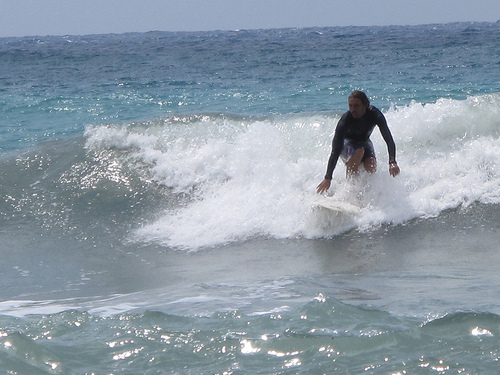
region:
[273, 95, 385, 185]
Person in water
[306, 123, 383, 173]
Person wearing black long sleeve shirt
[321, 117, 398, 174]
Person wearing dark bottoms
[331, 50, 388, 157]
Person has dark hair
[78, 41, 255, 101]
Water is blue and clear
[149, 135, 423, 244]
Waves rolling in by person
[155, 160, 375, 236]
Wave has white cap on it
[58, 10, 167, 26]
Sky is clear and blue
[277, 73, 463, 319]
Person is surfing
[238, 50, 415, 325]
Person is crouched down close to water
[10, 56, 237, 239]
Ocean wave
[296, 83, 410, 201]
Male surfing the wave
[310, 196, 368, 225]
Surfboard in wave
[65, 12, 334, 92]
ocean behind wave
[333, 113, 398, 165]
Male is wearing a wet suit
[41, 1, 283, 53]
Horizon above the ocean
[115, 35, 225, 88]
Ocean is very choppy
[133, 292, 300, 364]
Reflection on water appears to be day time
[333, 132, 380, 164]
Male surfer is wearing board shorts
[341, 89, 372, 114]
Male surfer has medium length hair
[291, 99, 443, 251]
a man surfing in the ocean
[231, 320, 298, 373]
sunlight reflecting on the surface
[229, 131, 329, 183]
white water spraying into the air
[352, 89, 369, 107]
wet dark hair on a head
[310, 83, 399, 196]
a man reaching for the surfboard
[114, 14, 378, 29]
the horizon over the water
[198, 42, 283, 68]
calm waves rippling in the water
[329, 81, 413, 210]
a man wearing black shirt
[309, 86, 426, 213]
a man wearing blue and black swim trunks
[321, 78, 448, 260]
a man trying to stand on a surfbaoard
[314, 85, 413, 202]
surfer surfing a wave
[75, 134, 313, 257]
wave crashing onto ocean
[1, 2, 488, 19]
ocean horizon against pale blue sky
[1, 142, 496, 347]
large body of water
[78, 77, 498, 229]
small wave with surfer riding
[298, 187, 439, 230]
white surfboard emerging from wave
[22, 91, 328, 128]
reflection of sunlight off water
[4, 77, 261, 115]
clear blue ocean water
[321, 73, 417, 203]
young male on surfboard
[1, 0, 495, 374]
surfer rides a wave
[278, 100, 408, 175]
the man is surfing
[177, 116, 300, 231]
there isa wave in the water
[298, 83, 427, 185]
the man has a black top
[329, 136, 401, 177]
the man is wearing shorts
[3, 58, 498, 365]
the photo was taken during the ay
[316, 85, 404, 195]
the man is wet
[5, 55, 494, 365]
the photo was taken during the day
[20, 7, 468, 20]
the sky is blue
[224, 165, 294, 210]
the water waves are white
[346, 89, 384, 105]
his hair is black